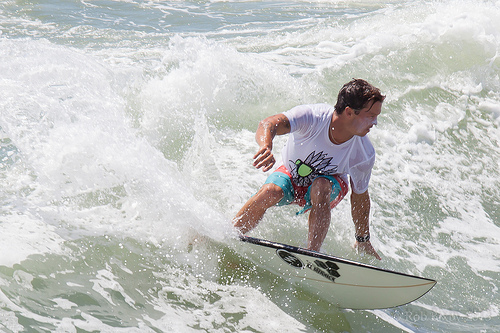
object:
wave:
[15, 17, 498, 218]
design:
[275, 247, 340, 284]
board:
[233, 232, 438, 314]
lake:
[278, 140, 393, 195]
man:
[231, 72, 389, 256]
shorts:
[234, 234, 440, 318]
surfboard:
[201, 232, 435, 309]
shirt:
[285, 112, 367, 189]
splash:
[33, 82, 199, 236]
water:
[2, 3, 497, 331]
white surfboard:
[232, 238, 437, 310]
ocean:
[2, 1, 498, 331]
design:
[287, 150, 338, 187]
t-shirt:
[281, 103, 376, 194]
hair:
[330, 77, 384, 120]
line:
[182, 197, 377, 296]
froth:
[30, 48, 245, 228]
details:
[238, 234, 432, 283]